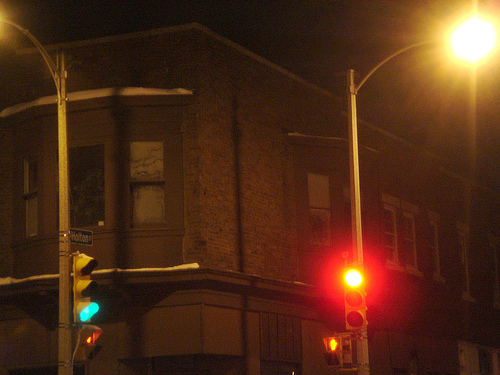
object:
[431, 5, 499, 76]
street light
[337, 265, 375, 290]
light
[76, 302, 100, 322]
green light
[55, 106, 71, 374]
pole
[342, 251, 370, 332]
signal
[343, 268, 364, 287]
right light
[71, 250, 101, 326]
signal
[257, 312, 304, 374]
small window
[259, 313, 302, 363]
blocks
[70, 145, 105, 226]
black window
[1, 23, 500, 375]
building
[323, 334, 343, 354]
smaller signal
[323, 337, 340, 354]
light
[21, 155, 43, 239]
window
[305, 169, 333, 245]
window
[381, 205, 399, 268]
window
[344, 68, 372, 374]
pole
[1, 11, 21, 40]
lamp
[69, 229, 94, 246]
street sign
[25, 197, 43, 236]
section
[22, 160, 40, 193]
section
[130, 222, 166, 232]
ledge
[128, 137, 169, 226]
window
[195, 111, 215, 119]
bricks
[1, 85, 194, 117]
snow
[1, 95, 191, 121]
ledge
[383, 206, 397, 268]
white frame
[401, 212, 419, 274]
window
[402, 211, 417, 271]
white frame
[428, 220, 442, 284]
window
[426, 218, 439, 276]
white frame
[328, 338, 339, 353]
orange light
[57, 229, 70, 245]
metal ring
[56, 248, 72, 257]
metal ring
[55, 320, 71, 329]
metal ring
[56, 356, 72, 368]
metal ring